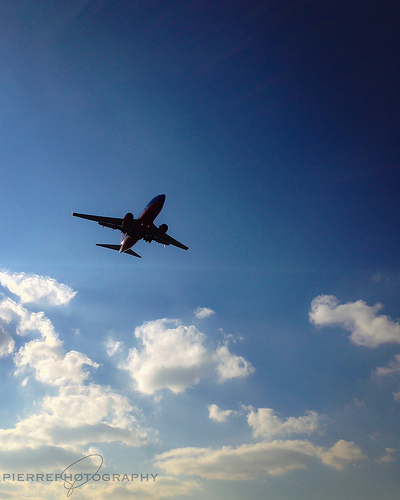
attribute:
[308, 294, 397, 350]
cloud — white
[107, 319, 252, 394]
cloud — white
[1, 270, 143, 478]
cloud — white, grey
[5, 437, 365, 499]
cloud — white, greyish, dark, grey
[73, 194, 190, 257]
airplane — flying, ascending, half red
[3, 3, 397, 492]
sky — sunny, blue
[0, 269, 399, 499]
clouds — dark, grouped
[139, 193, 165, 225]
nose — pointing upwards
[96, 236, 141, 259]
tail — triangular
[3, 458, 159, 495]
logo — pierre photography, translucent